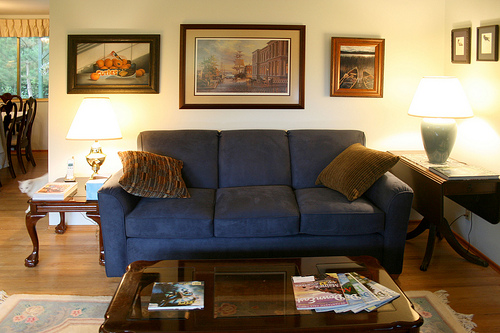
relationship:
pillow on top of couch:
[116, 148, 193, 200] [98, 128, 411, 277]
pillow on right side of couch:
[116, 148, 193, 200] [98, 128, 411, 277]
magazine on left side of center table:
[292, 269, 344, 312] [104, 257, 424, 330]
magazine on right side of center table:
[150, 278, 209, 313] [104, 257, 424, 330]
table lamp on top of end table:
[71, 96, 125, 179] [24, 170, 112, 269]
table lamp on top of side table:
[403, 75, 471, 168] [385, 145, 498, 274]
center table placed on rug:
[104, 257, 424, 330] [3, 285, 476, 332]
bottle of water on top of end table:
[63, 148, 77, 185] [24, 170, 112, 269]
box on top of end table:
[84, 179, 105, 201] [24, 170, 112, 269]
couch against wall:
[98, 128, 411, 277] [48, 3, 498, 247]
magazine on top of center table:
[292, 269, 344, 312] [104, 257, 424, 330]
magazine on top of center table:
[150, 278, 209, 313] [104, 257, 424, 330]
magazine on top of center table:
[326, 270, 376, 313] [104, 257, 424, 330]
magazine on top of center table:
[346, 272, 396, 313] [104, 257, 424, 330]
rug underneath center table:
[3, 285, 476, 332] [104, 257, 424, 330]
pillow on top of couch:
[315, 143, 402, 200] [98, 128, 411, 277]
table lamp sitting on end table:
[71, 96, 125, 179] [24, 170, 112, 269]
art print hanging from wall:
[176, 23, 305, 112] [48, 3, 498, 247]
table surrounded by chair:
[1, 108, 26, 173] [1, 92, 23, 112]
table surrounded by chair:
[1, 108, 26, 173] [19, 99, 35, 168]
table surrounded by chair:
[1, 108, 26, 173] [0, 101, 18, 181]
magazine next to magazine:
[326, 270, 376, 313] [346, 272, 396, 313]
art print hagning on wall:
[176, 23, 305, 112] [48, 3, 498, 247]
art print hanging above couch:
[176, 23, 305, 112] [98, 128, 411, 277]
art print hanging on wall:
[176, 23, 305, 112] [48, 3, 498, 247]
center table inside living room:
[104, 257, 424, 330] [22, 0, 499, 331]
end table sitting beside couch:
[24, 170, 112, 269] [98, 128, 411, 277]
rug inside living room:
[3, 285, 476, 332] [22, 0, 499, 331]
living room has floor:
[22, 0, 499, 331] [2, 175, 499, 329]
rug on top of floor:
[3, 285, 476, 332] [2, 175, 499, 329]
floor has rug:
[2, 175, 499, 329] [3, 285, 476, 332]